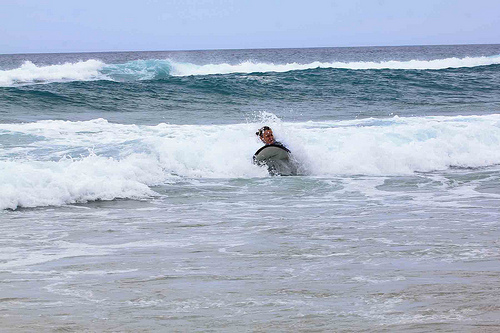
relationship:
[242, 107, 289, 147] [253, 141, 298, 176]
man on surfboard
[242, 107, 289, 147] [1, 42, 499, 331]
man surfing in ocean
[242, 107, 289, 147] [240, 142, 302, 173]
man on board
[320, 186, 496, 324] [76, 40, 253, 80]
water in front of waves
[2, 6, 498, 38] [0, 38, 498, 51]
sky above horizon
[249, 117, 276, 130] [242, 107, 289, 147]
head of man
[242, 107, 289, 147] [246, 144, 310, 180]
man on board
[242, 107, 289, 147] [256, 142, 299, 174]
man riding board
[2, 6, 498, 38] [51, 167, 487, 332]
sky above ocean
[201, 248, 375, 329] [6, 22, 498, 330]
water on shore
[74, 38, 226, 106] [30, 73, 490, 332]
wave in ocean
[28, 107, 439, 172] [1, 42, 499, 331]
wave of ocean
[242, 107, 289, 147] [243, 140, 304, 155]
man on board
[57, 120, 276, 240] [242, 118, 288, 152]
water above man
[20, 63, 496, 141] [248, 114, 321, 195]
swell behind surfer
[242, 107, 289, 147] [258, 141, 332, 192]
man on board